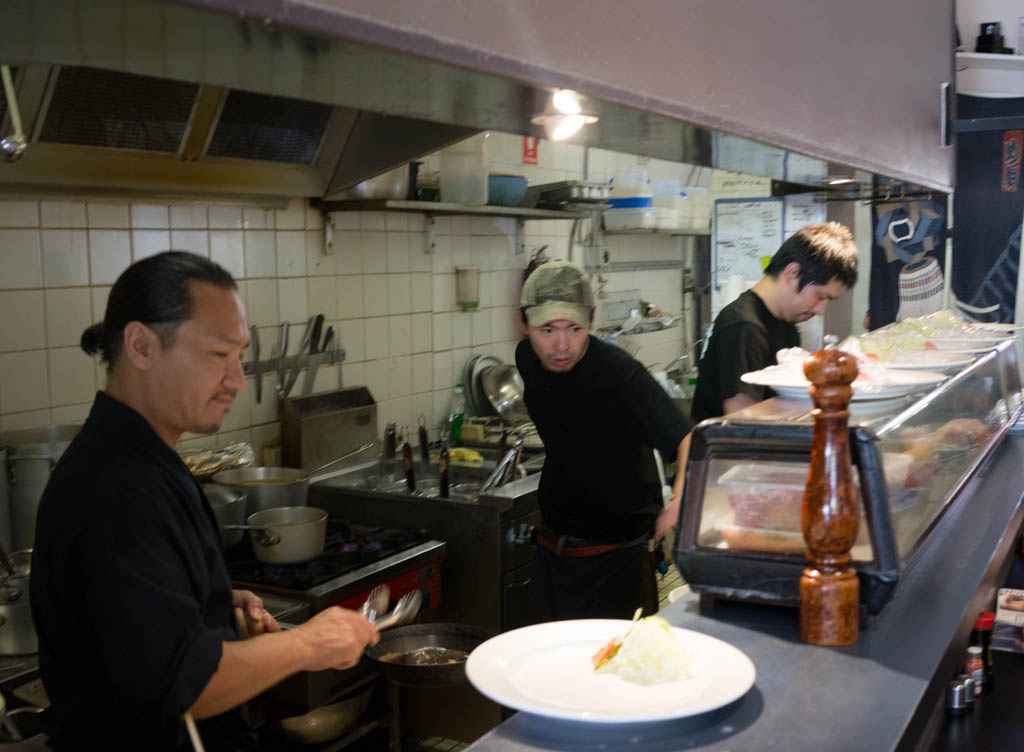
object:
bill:
[525, 301, 593, 328]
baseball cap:
[518, 260, 594, 326]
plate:
[463, 617, 754, 723]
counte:
[460, 333, 1022, 752]